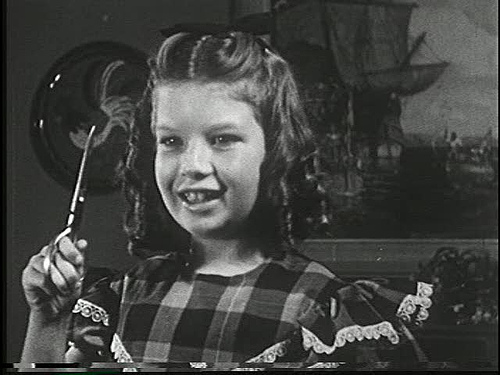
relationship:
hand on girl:
[20, 237, 86, 321] [18, 36, 431, 356]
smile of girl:
[176, 185, 227, 211] [139, 38, 313, 283]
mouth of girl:
[155, 174, 233, 224] [42, 44, 391, 341]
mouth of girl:
[171, 186, 222, 216] [24, 40, 484, 323]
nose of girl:
[178, 142, 207, 175] [18, 36, 431, 356]